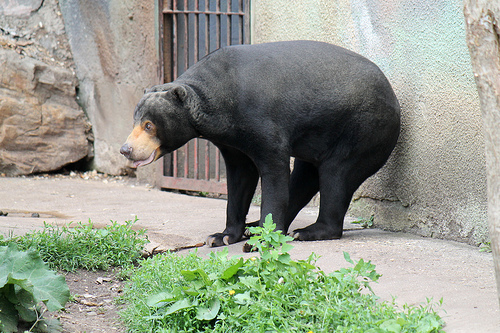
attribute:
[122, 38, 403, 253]
bear — black, tan, big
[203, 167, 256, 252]
leg — black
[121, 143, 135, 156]
snout — brown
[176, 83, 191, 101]
ear — black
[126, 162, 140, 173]
tongue — pink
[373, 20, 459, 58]
wall — stone, granite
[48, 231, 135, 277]
grass — green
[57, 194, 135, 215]
sidewalk — paved, gre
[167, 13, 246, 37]
bars — metal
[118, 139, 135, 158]
nose — black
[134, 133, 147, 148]
muzzle — light brown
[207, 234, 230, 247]
claws — white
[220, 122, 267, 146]
fur — black